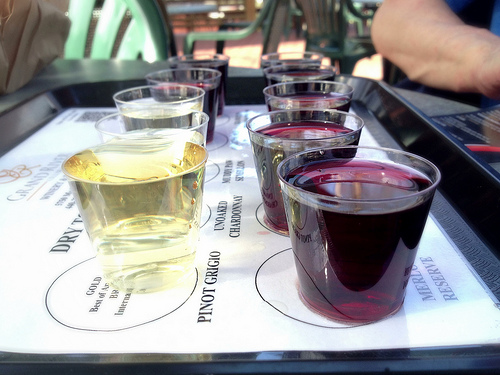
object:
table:
[0, 54, 498, 90]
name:
[192, 249, 222, 324]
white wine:
[63, 136, 205, 294]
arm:
[365, 4, 498, 120]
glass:
[237, 106, 370, 242]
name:
[405, 252, 462, 304]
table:
[159, 5, 218, 15]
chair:
[184, 2, 284, 66]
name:
[12, 150, 71, 202]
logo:
[0, 157, 46, 184]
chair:
[36, 0, 178, 63]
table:
[20, 47, 464, 114]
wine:
[278, 157, 442, 328]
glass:
[252, 49, 329, 68]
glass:
[56, 132, 213, 299]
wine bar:
[2, 1, 499, 371]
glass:
[276, 146, 440, 324]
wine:
[247, 118, 365, 237]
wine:
[266, 93, 352, 125]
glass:
[263, 77, 356, 126]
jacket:
[1, 0, 76, 97]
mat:
[0, 95, 499, 360]